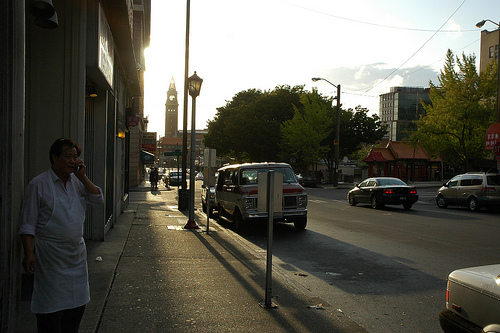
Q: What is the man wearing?
A: An apron.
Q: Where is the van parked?
A: On the street.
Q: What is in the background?
A: A tree.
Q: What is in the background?
A: Trees.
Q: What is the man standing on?
A: The sidewalk.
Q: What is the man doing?
A: Talking on the phone.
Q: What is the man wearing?
A: An apron.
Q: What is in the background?
A: A tree.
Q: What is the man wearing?
A: Apron.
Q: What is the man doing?
A: Talking on phone.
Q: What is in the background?
A: Green trees.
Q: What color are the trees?
A: Green.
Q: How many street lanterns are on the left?
A: 1.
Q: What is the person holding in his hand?
A: Phone.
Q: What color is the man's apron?
A: White.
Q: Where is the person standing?
A: Sidewalk.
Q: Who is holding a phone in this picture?
A: Cook.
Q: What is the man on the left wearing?
A: Apron.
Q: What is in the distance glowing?
A: Clock Tower.